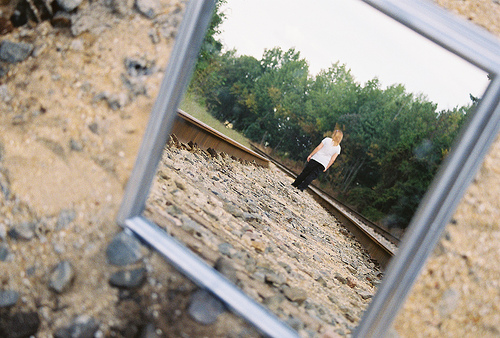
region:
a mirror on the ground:
[94, 0, 484, 328]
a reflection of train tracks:
[166, 97, 399, 277]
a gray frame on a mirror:
[116, 0, 495, 329]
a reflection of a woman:
[288, 117, 362, 195]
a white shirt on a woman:
[310, 115, 349, 172]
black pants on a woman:
[285, 158, 339, 189]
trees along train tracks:
[232, 36, 446, 224]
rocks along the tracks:
[145, 156, 382, 333]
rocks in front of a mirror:
[100, 227, 232, 333]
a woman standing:
[283, 125, 353, 203]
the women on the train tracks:
[294, 122, 352, 200]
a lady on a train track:
[108, 32, 433, 257]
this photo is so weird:
[234, 69, 351, 202]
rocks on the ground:
[29, 68, 101, 216]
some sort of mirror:
[432, 10, 489, 132]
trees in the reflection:
[306, 57, 448, 127]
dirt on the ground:
[33, 253, 83, 287]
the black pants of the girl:
[302, 150, 339, 197]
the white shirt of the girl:
[327, 123, 342, 176]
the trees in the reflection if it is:
[273, 37, 452, 137]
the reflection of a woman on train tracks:
[287, 104, 358, 219]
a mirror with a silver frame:
[107, 0, 497, 336]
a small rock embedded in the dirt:
[41, 238, 87, 306]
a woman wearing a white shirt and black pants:
[287, 110, 349, 213]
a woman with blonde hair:
[283, 119, 353, 203]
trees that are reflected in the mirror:
[178, 0, 495, 262]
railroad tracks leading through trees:
[162, 94, 415, 279]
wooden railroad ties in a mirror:
[127, 195, 370, 336]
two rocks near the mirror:
[97, 213, 156, 301]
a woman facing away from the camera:
[289, 118, 354, 197]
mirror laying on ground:
[119, 0, 498, 336]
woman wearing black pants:
[292, 127, 342, 190]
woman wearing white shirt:
[313, 135, 341, 169]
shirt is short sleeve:
[310, 135, 342, 168]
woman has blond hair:
[331, 129, 342, 145]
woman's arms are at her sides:
[306, 137, 326, 164]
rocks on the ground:
[101, 232, 142, 264]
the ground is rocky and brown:
[2, 18, 263, 336]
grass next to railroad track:
[178, 93, 265, 148]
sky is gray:
[214, 0, 490, 112]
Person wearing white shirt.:
[301, 132, 371, 209]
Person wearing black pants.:
[300, 165, 365, 249]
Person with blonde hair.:
[321, 118, 358, 197]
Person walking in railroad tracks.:
[213, 87, 377, 221]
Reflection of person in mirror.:
[240, 119, 347, 280]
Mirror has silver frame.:
[133, 175, 205, 320]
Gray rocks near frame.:
[87, 224, 197, 326]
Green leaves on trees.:
[333, 67, 397, 210]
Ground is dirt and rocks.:
[33, 84, 103, 255]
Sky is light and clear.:
[346, 31, 462, 102]